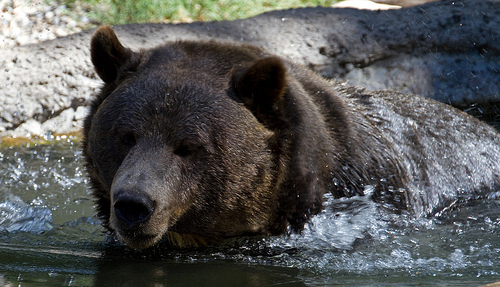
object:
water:
[316, 215, 358, 246]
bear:
[46, 20, 500, 268]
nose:
[101, 185, 165, 228]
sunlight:
[24, 52, 55, 97]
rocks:
[23, 51, 67, 82]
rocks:
[403, 23, 445, 48]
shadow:
[417, 12, 499, 91]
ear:
[215, 48, 309, 133]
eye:
[167, 140, 199, 160]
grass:
[95, 2, 139, 18]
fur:
[141, 70, 173, 98]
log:
[18, 237, 69, 273]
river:
[0, 96, 500, 287]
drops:
[443, 238, 470, 258]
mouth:
[106, 220, 178, 253]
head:
[66, 16, 325, 255]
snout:
[100, 141, 189, 240]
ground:
[47, 6, 82, 32]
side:
[15, 15, 60, 39]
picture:
[0, 1, 500, 287]